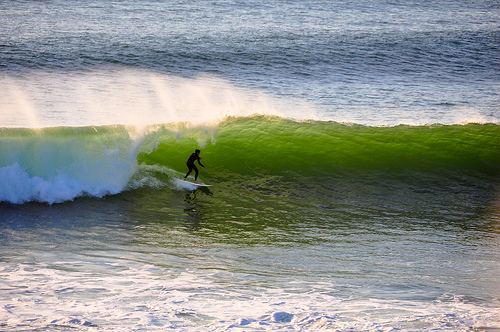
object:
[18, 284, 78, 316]
ripples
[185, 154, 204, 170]
wet suit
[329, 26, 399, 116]
wave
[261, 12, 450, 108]
water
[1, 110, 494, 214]
wave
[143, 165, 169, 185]
ripple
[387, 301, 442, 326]
wave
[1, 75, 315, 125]
white spray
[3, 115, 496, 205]
crashing waves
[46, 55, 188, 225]
wave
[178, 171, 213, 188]
surfboard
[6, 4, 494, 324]
shot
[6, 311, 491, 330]
shoreline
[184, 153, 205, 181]
wetsuit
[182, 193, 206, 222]
reflection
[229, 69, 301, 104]
wall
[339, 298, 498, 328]
ripples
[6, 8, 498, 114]
ocean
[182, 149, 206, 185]
man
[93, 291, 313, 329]
ripples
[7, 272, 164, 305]
ripples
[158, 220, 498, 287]
ripples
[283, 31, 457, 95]
ripples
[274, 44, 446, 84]
ripple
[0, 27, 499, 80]
wave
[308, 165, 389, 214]
water